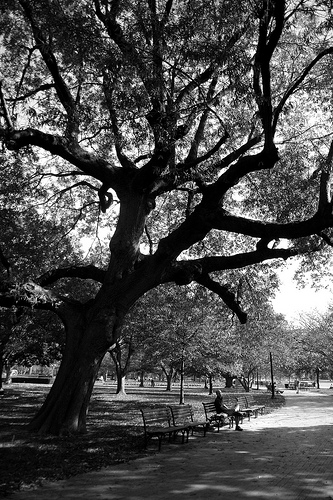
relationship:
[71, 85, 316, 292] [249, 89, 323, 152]
tree has branch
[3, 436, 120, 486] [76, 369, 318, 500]
leave on ground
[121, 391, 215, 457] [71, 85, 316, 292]
bench under tree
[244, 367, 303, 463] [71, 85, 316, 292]
trail in front of tree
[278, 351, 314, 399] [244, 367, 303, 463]
person on trail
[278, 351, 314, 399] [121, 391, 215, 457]
person on bench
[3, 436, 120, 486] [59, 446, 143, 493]
leave on path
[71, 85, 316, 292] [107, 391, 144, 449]
tree on grass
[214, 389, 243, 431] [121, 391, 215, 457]
person on bench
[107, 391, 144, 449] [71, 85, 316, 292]
grass under tree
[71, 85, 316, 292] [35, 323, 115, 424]
tree has trunk